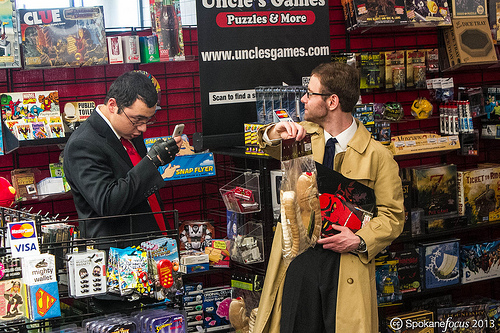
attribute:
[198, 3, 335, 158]
banner — black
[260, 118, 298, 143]
hand — man's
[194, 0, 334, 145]
sign —  black and white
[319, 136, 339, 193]
tie —  black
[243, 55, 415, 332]
man — in the foreground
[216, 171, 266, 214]
bin — clear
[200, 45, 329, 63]
letters — white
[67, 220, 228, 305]
multiple items —  multiple,  display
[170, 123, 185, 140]
phone —  Man's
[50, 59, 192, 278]
men —  two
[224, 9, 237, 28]
letter — white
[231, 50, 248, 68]
letter — white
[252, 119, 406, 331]
trench coat —  trench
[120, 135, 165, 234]
tie —  red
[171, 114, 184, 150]
phone —  man's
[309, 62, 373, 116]
hair —  dark,  Man's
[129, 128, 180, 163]
fingerless glove —  finger-less,  man's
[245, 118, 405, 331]
coat —  tan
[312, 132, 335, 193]
tie —  dark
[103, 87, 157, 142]
face — man's